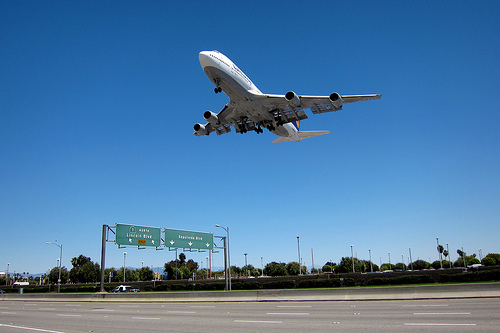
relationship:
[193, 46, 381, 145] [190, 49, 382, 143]
plane has plane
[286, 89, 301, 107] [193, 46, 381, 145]
engine on side of plane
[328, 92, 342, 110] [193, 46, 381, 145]
engines on side of plane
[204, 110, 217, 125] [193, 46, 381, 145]
engine on side of plane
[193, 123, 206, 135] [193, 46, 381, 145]
engine on side of plane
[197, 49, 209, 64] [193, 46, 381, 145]
nose of plane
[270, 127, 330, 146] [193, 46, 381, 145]
tail of plane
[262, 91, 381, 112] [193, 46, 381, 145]
wing of plane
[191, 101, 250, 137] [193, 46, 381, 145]
wings of plane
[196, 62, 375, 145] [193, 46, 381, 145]
underside of plane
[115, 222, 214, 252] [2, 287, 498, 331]
signs on street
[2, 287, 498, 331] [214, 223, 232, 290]
street has light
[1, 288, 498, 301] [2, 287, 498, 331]
barrier between lanes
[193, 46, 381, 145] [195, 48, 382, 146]
plane has taken off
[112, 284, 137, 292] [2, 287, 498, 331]
car on highway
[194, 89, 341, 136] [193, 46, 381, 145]
engines on plane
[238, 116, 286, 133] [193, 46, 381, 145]
landing gear on plane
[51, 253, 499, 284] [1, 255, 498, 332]
trees at bottom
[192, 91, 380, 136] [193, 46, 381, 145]
wings of plane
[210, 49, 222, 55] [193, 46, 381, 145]
windows on plane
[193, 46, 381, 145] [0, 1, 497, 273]
plane in sky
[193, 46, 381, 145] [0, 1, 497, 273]
plane in mid air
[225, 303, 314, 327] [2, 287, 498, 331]
white lines on road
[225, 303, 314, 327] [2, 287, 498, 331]
white lines on street